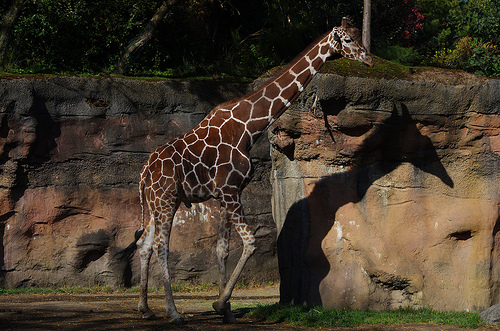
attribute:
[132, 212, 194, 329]
legs — hind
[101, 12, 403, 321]
giraffe — walking 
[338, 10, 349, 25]
horns — small, brown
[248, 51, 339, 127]
neck — long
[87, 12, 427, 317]
giraffe — brown and white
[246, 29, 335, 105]
mane — long, brown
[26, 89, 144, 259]
wall — stone, black and brown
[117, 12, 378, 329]
giraffe — tall, brown, white